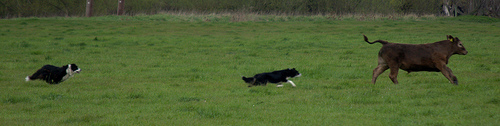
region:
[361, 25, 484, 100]
large animal running in field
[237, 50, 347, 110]
small dog running in field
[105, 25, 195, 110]
green grass in field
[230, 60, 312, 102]
dog with black body and white feet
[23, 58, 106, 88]
dog jumping off the ground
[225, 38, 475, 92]
dog chasing large cow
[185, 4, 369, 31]
tall grass in field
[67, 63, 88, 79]
white and black face of dog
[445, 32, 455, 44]
yellow tag on cows ear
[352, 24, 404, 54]
long brown cow tail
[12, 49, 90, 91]
This is a dog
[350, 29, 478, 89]
This is a calf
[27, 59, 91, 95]
The dog is running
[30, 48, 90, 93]
The dog is black and white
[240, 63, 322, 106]
The cat is running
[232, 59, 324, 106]
The cat is black and white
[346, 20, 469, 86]
The calf is running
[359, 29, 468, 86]
The calf is brown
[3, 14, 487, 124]
Animals running in a field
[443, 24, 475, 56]
head of a cow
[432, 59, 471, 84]
leg of a cow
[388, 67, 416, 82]
leg of a cow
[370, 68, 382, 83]
leg of a cow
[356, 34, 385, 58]
tail of a cow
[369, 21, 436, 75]
body of a cow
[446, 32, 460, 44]
ear of a cow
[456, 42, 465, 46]
eye of a cow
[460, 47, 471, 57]
mouth of a cow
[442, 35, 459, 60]
neck of a cow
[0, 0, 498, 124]
a green grassy field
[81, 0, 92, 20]
a wooden fence post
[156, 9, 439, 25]
tall grass growing along a fence line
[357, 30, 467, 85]
a brown steer running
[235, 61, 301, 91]
a black and white dog directly behind a steer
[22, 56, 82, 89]
a black and white dog behind another dog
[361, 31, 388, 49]
the brown tail of a steer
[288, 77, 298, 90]
the white leg of a dog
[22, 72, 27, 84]
the white tip on the end of a dog's tail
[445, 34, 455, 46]
a yellow tag in a steer's ear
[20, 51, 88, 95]
This is a dog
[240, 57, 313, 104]
This is a dog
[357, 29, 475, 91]
This is a calf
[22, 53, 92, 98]
The dog is running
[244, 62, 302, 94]
The dog is running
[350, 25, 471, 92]
The calf is running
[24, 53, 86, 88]
The dog is black and white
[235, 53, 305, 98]
The dog is black and white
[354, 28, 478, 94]
The calf is brown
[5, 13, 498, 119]
Animals are running in a field